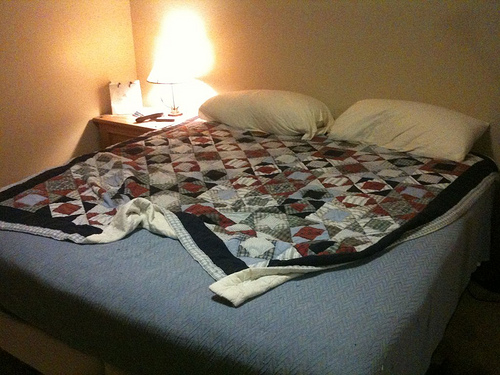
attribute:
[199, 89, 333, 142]
pillow — white, covered, rumpled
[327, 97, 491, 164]
pillow — white, covered, rumpled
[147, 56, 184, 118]
lamp — bright, on, lit, orange light, bright orange, turned on, bedside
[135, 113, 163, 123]
remote control — for television, black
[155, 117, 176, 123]
remote control — for television, black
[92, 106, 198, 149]
bedside table — brown, wooden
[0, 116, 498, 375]
bed — unmade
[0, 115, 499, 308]
quilt — patterned, multi colored, red, white, rumpled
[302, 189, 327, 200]
square — black, navy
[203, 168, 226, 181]
square — black, navy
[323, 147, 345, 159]
square — black, navy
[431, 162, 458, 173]
square — black, navy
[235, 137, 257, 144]
square — black, navy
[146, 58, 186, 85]
lamp shade — white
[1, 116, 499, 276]
lining — black, border, navy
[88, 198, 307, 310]
bottom — white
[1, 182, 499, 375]
sheet — blue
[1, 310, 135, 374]
box spring — white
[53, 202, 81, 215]
square — red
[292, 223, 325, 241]
square — red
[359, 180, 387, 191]
square — red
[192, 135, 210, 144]
square — red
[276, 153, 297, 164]
square — white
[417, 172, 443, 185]
square — white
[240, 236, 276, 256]
square — white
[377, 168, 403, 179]
square — white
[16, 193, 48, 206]
square — white